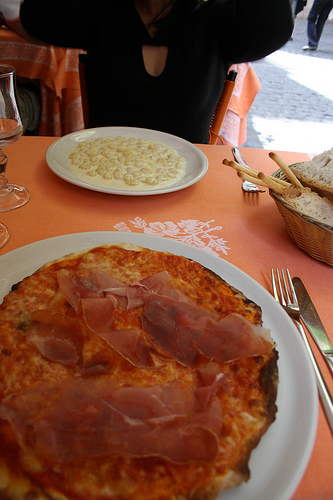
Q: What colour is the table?
A: Orange.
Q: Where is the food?
A: On the plate.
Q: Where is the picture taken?
A: A cafe.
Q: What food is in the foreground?
A: Pizza.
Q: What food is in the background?
A: Pasta.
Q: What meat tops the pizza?
A: Prosciutto.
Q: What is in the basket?
A: Bread and breadsticks.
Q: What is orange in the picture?
A: A tablecloth.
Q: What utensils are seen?
A: Forks and knife.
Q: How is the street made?
A: Of cobblestones.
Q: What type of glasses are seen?
A: Wine.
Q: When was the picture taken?
A: Afternoon.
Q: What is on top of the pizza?
A: Ham.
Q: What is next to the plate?
A: A fork and a knife.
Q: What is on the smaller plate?
A: Pasta.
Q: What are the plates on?
A: An orange table.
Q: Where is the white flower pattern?
A: On top of the orange table.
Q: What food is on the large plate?
A: A pizza.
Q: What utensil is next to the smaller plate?
A: A fork.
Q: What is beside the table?
A: A chair.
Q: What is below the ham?
A: Cheese.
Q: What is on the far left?
A: Glasses.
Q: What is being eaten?
A: Pizza.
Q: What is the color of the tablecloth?
A: Orange.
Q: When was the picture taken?
A: During the day.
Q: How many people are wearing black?
A: 2.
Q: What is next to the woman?
A: White plate.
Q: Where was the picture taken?
A: At a restaurant.